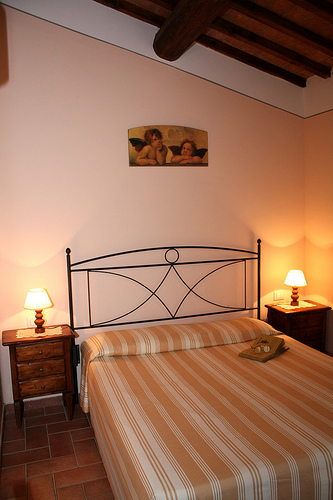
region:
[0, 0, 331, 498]
A bed in a bedroom.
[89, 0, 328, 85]
Wooden posts along the ceiling.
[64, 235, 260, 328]
A black metal headboard.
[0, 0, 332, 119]
White border around the upper part of the walls.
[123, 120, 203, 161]
A picture of two angels.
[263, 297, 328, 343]
Nightstand on the right side of the bed.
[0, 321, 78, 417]
Nightstand on the left side of the bed.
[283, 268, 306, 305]
Brown lamp with a white shade.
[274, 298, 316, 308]
White doily on top of the nightstand.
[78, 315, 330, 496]
Orange and white bedspread on the bed.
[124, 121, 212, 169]
small picture on wall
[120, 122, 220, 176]
two angels on a picture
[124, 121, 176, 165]
small angel on picture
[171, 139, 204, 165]
small angel resting on arms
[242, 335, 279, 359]
book on top of bed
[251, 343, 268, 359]
glasses on top of book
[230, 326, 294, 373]
book and glasses on bed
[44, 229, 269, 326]
black metal bed frame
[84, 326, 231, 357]
pillows on back of bed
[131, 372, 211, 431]
orange and white stripes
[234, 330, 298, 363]
brown towels on the bed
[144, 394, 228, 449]
brown and white sheets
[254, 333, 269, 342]
black letters on towel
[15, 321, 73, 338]
small white doily on table top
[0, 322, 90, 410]
small brown bedside table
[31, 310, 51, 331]
brown frame on lamp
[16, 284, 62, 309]
white lamp shade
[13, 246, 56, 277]
light illuminating the wall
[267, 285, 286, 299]
white wall outlet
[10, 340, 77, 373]
drawer on brown table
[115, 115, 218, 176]
paintings on a wall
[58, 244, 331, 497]
a bed and a bed cradle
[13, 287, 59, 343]
lamp on a table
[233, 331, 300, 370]
a book on top of bed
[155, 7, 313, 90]
ceiling of a building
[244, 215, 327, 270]
shadows on a wall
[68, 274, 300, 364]
pillows on a bed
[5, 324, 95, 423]
a small table near bed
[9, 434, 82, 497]
brick tiles on floor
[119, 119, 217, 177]
a picture frame painting on the wall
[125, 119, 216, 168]
picture with two angels over the bed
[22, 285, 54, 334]
small bedside lamp with a wooden base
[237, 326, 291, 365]
open book with eyeglasses on it on the bed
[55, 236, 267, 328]
black metal bed frame with a simple design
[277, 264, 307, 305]
small bedside lamp on a small wooden table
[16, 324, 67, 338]
small white doily the lamp is on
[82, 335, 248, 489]
brown plaid bedspread on the bed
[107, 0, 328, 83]
exposed wood beams in the ceiling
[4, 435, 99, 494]
brown tiled floor of the bedroom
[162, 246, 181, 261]
small circle design in the bed frame